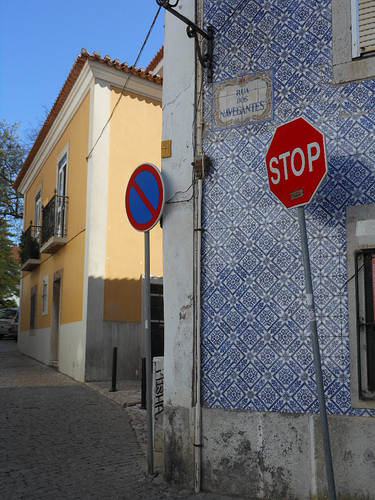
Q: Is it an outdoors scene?
A: Yes, it is outdoors.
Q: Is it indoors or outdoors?
A: It is outdoors.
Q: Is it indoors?
A: No, it is outdoors.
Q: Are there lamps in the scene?
A: No, there are no lamps.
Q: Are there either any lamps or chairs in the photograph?
A: No, there are no lamps or chairs.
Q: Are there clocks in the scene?
A: No, there are no clocks.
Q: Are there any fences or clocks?
A: No, there are no clocks or fences.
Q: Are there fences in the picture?
A: No, there are no fences.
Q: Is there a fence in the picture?
A: No, there are no fences.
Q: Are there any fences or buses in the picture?
A: No, there are no fences or buses.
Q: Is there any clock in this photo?
A: No, there are no clocks.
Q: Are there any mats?
A: No, there are no mats.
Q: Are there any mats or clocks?
A: No, there are no mats or clocks.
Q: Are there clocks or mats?
A: No, there are no mats or clocks.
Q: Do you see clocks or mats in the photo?
A: No, there are no mats or clocks.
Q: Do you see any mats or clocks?
A: No, there are no mats or clocks.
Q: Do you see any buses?
A: No, there are no buses.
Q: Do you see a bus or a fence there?
A: No, there are no buses or fences.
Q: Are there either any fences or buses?
A: No, there are no buses or fences.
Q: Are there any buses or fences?
A: No, there are no buses or fences.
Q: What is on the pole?
A: The sign is on the pole.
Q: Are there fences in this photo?
A: No, there are no fences.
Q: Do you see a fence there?
A: No, there are no fences.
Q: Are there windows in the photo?
A: Yes, there is a window.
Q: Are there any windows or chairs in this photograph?
A: Yes, there is a window.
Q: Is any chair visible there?
A: No, there are no chairs.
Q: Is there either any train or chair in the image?
A: No, there are no chairs or trains.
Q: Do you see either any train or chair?
A: No, there are no chairs or trains.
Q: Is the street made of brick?
A: No, the street is made of cobblestone.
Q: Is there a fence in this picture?
A: No, there are no fences.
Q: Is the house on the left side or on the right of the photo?
A: The house is on the left of the image.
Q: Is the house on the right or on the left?
A: The house is on the left of the image.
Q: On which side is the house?
A: The house is on the left of the image.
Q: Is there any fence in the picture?
A: No, there are no fences.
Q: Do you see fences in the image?
A: No, there are no fences.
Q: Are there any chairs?
A: No, there are no chairs.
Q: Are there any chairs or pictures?
A: No, there are no chairs or pictures.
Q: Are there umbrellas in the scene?
A: No, there are no umbrellas.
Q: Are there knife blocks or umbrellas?
A: No, there are no umbrellas or knife blocks.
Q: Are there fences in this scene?
A: No, there are no fences.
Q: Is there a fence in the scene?
A: No, there are no fences.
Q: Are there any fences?
A: No, there are no fences.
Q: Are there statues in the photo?
A: No, there are no statues.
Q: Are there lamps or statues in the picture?
A: No, there are no statues or lamps.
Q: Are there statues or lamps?
A: No, there are no statues or lamps.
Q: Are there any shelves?
A: No, there are no shelves.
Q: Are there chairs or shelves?
A: No, there are no shelves or chairs.